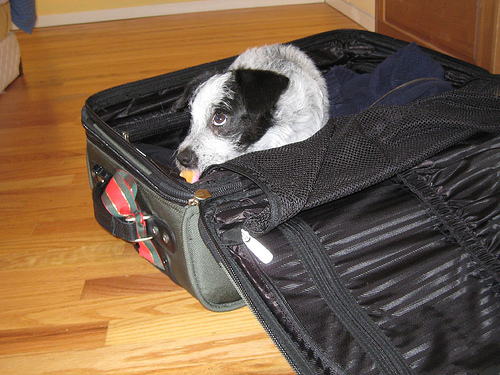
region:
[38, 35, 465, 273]
small dog is laying in suitcase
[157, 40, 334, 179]
dog is black and white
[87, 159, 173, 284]
green and red ribbon on luggage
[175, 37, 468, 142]
dog is laying on top of clothes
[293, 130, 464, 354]
interior of suitcase appears to be black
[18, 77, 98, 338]
suitcase is on wooden floor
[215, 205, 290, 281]
silver zipper pull inside suitcase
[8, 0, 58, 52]
bottom edge of a man's blue necktie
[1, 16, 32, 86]
another piece of luggage or furniture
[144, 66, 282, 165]
dog has sad expression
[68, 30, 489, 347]
olive green suitcase with red and green ribbon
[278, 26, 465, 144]
navy blue sweater in suitcase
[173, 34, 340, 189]
black and white dog lying down in suitcase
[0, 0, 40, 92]
tan mattress with white bedboard beneath it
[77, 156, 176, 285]
red and green ribbon attached to suitcase handle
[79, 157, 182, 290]
suitcase handle with red, green, and gold ribbon attached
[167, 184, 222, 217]
gold zipper for closing/opening a suitcase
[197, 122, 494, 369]
cover of an olive green suitcase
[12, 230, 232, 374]
golden hardwood flooring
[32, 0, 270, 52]
white wall trim on yellow painted wall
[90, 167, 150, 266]
red and grey ribbon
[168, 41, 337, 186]
black and white dog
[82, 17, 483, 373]
open black suitcase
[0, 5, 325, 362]
brown wood floor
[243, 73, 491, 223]
mesh suitcase divider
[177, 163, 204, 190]
yellow and pink dog toy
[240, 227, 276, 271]
silver zipper tab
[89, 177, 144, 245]
black suitcase handle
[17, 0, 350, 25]
white baseboard along bottom of wall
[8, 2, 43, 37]
black necktie in top left corner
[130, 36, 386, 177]
a black and white dog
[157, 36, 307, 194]
the head of a dog peeping out of a suitcase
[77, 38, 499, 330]
an open black suitcase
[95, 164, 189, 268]
a ribbon on a suitcase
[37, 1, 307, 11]
a white floorboard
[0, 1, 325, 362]
a wood floor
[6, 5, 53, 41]
a blue curtain covering a floorboard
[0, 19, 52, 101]
a box spring on a floor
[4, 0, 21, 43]
a mattress on a box spring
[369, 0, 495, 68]
a brown wooden door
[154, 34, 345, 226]
a dog laying in a piece of luggage.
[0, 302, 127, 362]
a section of a wood floor.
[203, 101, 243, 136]
the left eye of a dog.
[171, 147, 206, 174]
the black nose of a dog.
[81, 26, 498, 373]
a large piece of luggage.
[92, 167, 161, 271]
a red and black strap.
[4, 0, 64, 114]
a piece of furniture in a room.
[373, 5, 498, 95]
a door in a bedroom.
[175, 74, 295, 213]
a cute dog head.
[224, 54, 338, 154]
a furry dog body.